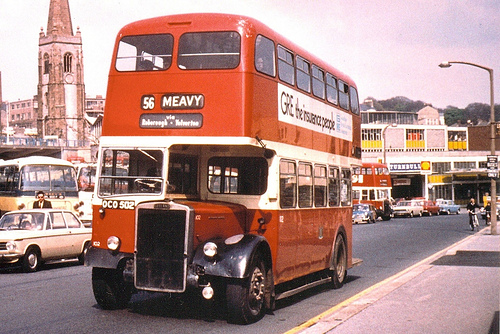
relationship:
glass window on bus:
[294, 52, 318, 100] [72, 3, 427, 299]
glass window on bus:
[303, 55, 332, 98] [75, 6, 398, 306]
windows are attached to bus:
[226, 32, 371, 111] [85, 12, 365, 324]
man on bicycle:
[466, 197, 475, 229] [459, 210, 491, 234]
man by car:
[33, 192, 50, 208] [2, 210, 115, 283]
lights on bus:
[194, 238, 235, 313] [85, 12, 365, 324]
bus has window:
[85, 12, 365, 324] [97, 144, 166, 191]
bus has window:
[85, 12, 365, 324] [204, 156, 265, 194]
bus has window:
[85, 12, 365, 324] [277, 158, 297, 205]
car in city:
[435, 200, 459, 214] [6, 4, 493, 333]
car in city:
[2, 205, 92, 274] [6, 4, 493, 333]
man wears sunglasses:
[33, 192, 50, 208] [33, 191, 43, 200]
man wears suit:
[33, 192, 50, 208] [32, 198, 53, 205]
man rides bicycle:
[466, 197, 475, 229] [464, 207, 482, 230]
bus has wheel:
[85, 12, 365, 324] [219, 245, 273, 328]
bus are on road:
[85, 12, 365, 324] [0, 208, 483, 331]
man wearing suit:
[24, 186, 52, 211] [32, 197, 52, 207]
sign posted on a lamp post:
[479, 146, 498, 175] [451, 62, 496, 234]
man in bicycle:
[461, 186, 485, 235] [474, 204, 497, 236]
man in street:
[461, 186, 485, 235] [0, 207, 495, 331]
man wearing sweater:
[466, 197, 475, 229] [462, 203, 482, 222]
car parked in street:
[435, 185, 464, 219] [0, 207, 495, 331]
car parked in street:
[0, 208, 92, 273] [0, 207, 495, 331]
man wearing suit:
[33, 192, 50, 208] [31, 194, 52, 206]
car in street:
[352, 200, 384, 225] [0, 207, 495, 331]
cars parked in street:
[358, 186, 463, 221] [0, 207, 495, 331]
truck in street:
[351, 157, 396, 218] [0, 207, 495, 331]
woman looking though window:
[184, 25, 234, 69] [170, 25, 245, 68]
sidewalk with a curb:
[290, 228, 496, 331] [283, 233, 483, 332]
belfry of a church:
[38, 51, 78, 75] [0, 0, 102, 154]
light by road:
[437, 63, 449, 68] [0, 208, 483, 331]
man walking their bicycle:
[466, 197, 475, 229] [465, 206, 483, 228]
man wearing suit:
[33, 192, 50, 208] [36, 197, 50, 209]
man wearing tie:
[33, 192, 50, 208] [32, 199, 42, 211]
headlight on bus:
[103, 233, 217, 257] [85, 12, 365, 324]